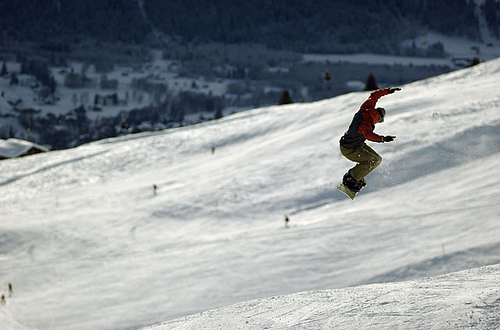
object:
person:
[328, 86, 401, 201]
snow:
[1, 52, 499, 329]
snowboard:
[336, 173, 368, 200]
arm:
[361, 118, 386, 144]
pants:
[341, 143, 382, 182]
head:
[373, 107, 386, 124]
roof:
[0, 138, 49, 158]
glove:
[383, 135, 397, 143]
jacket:
[337, 87, 389, 149]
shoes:
[342, 172, 366, 191]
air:
[2, 2, 499, 329]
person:
[283, 213, 291, 230]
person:
[152, 183, 158, 196]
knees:
[363, 155, 377, 166]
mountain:
[1, 1, 499, 153]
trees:
[9, 70, 21, 87]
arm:
[361, 86, 391, 109]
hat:
[373, 106, 388, 123]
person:
[210, 145, 215, 154]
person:
[7, 282, 15, 292]